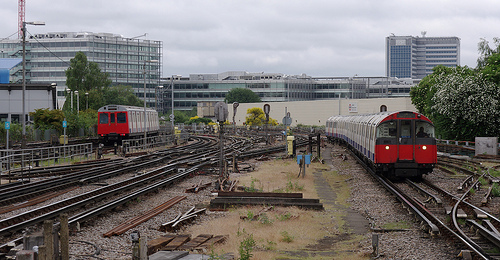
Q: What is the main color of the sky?
A: White.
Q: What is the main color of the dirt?
A: Brown.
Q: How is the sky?
A: Cloudy.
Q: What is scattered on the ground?
A: Track pieces.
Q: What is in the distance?
A: Buildings.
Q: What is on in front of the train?
A: Headlights.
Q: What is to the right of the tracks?
A: Trees.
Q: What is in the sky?
A: Clouds.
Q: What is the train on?
A: Tracks.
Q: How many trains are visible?
A: Two.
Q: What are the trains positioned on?
A: Tracks.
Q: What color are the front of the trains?
A: Red.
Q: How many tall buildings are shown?
A: Two.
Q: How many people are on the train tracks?
A: Zero.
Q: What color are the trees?
A: Green.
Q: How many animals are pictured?
A: Zero.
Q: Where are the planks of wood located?
A: Ground.